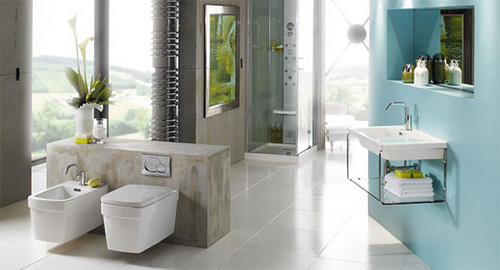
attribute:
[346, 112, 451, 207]
sink — white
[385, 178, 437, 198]
towels — white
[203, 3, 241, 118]
picture — framed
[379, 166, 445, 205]
towels — white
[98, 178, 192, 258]
toilet — white, contemporary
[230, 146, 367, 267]
tiles — large, white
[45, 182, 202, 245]
deep toilet — square, mounted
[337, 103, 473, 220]
sink — square, mounted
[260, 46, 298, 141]
shelf shower — white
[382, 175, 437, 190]
towel — folded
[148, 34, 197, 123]
pole — tall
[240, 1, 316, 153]
shower — stand up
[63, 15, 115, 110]
plant — flowering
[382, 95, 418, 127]
faucet — silver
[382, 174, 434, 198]
towel — folded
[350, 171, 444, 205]
shelf — glass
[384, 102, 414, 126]
faucet — silver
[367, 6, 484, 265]
wall — light blue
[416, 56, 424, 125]
lotion — white 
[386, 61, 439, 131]
lotion — white 